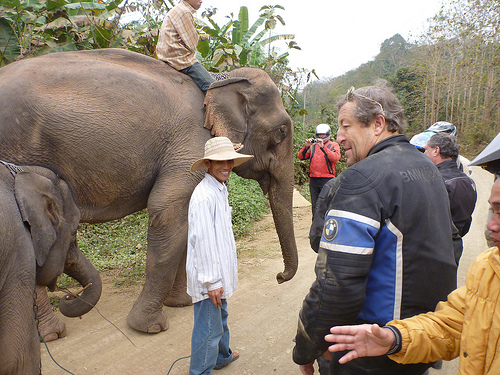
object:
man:
[292, 83, 464, 374]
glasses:
[345, 86, 385, 114]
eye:
[278, 124, 288, 140]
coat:
[297, 140, 341, 179]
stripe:
[301, 143, 317, 164]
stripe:
[324, 143, 336, 174]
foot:
[126, 282, 170, 334]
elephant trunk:
[263, 155, 301, 285]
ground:
[37, 287, 208, 374]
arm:
[296, 179, 379, 350]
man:
[297, 123, 341, 222]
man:
[422, 133, 477, 266]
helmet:
[315, 123, 331, 144]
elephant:
[0, 47, 301, 343]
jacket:
[435, 159, 477, 238]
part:
[316, 204, 366, 254]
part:
[442, 170, 475, 195]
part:
[472, 247, 497, 307]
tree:
[388, 66, 428, 128]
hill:
[301, 32, 412, 111]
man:
[153, 0, 216, 94]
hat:
[190, 136, 255, 172]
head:
[203, 148, 235, 182]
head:
[335, 85, 406, 167]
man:
[324, 167, 500, 374]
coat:
[388, 246, 500, 374]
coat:
[291, 133, 458, 374]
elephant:
[0, 157, 105, 374]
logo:
[323, 218, 339, 241]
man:
[185, 134, 259, 375]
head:
[201, 66, 296, 194]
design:
[312, 209, 402, 323]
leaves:
[48, 0, 157, 56]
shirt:
[184, 172, 240, 305]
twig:
[55, 282, 139, 349]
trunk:
[59, 240, 103, 318]